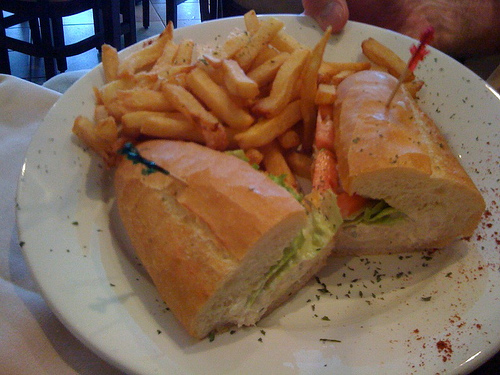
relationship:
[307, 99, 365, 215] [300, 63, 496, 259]
tomato in sandwich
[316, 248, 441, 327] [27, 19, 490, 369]
herbs are in plate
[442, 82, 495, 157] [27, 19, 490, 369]
spices are in plate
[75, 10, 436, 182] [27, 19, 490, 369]
french fries are on plate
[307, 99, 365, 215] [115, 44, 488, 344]
tomato are on sandwich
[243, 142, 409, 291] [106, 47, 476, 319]
lettuce on sandwich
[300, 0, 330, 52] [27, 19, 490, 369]
thumb holding plate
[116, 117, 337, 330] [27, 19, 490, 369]
sandwich on plate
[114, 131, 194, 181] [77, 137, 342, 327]
toothpick stuck in sandwich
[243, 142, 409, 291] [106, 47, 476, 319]
lettuce in sandwich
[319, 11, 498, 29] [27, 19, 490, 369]
person holding plate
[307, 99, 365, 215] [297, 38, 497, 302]
tomato on sandwich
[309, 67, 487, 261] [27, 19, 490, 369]
sandwich on plate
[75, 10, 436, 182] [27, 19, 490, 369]
french fries on plate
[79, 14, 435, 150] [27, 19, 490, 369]
fries on plate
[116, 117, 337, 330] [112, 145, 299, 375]
sandwich halve on white bread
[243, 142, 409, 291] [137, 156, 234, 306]
lettuce and tomato on bread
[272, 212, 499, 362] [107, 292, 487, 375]
seasoning and garnish sprinkled on a white plate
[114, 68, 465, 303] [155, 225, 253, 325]
meal with french friend and a sandwich on white bread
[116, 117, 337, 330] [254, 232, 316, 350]
sandwich with turkey and lettuce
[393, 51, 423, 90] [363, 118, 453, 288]
toothpick with red top holding sandwich together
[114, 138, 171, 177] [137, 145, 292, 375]
toothpick with blue top stuck in sandwich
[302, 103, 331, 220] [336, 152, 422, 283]
red tomato slice hanging off bread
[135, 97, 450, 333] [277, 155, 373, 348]
sandwich cut in half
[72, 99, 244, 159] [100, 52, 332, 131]
pile of french fries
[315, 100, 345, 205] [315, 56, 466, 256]
slice of tomato on sandwich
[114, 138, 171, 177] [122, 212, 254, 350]
toothpick on a sandwich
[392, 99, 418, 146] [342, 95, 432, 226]
toothpick stuck in a sandwich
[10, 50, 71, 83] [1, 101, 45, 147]
chairs on floor in restaurant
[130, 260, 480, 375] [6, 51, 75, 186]
plate full of food from restaurant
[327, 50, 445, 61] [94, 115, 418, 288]
hand that holding plate of food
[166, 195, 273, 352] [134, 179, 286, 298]
half of a sub sandwich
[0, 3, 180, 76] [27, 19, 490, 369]
chairs behind plate